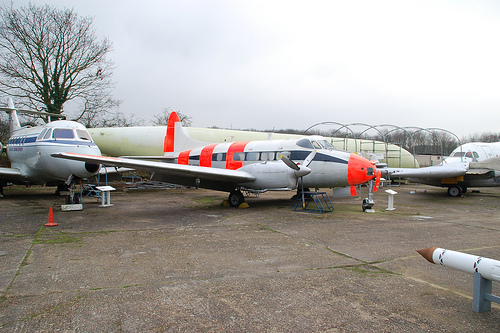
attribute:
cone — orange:
[33, 202, 58, 221]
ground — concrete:
[0, 169, 500, 331]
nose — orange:
[348, 154, 379, 187]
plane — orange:
[50, 112, 380, 214]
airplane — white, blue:
[0, 94, 134, 205]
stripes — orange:
[174, 140, 251, 171]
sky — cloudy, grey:
[75, 0, 498, 129]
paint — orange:
[348, 149, 379, 188]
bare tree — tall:
[0, 0, 115, 118]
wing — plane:
[50, 142, 254, 190]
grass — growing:
[28, 226, 76, 247]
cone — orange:
[44, 202, 58, 232]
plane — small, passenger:
[112, 131, 394, 211]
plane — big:
[76, 114, 425, 200]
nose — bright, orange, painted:
[347, 152, 383, 194]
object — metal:
[298, 116, 459, 154]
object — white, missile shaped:
[412, 234, 498, 322]